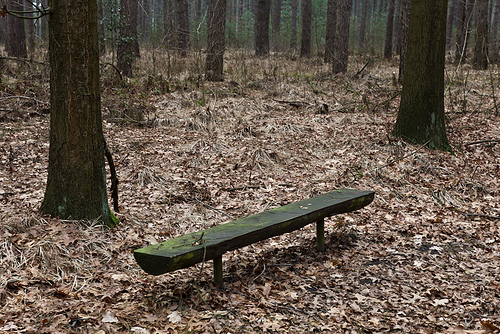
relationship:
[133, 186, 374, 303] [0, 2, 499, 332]
wooden bench in forest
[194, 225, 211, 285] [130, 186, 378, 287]
twig on wooden bench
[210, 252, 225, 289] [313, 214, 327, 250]
chair stand for leg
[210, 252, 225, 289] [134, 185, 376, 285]
chair stand for bench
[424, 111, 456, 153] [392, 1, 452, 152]
moss growing on base of tree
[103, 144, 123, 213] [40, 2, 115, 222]
branch leaning against tree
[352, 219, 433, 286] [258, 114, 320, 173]
leaves on ground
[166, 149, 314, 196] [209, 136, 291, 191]
leaves on ground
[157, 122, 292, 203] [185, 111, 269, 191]
leaves on ground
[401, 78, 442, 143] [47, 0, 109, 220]
trunk of a tree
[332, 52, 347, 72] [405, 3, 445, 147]
trunk of a tree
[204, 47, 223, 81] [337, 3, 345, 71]
trunk of a tree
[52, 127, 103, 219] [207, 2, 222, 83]
trunk of a tree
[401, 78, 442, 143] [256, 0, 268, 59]
trunk of a tree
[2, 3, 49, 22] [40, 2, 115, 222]
branch of a tree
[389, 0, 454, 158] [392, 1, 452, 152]
trunk of a tree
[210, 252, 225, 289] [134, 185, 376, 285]
chair stand of bench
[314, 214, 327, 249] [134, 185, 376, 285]
leg of bench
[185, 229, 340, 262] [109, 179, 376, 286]
leaves under bench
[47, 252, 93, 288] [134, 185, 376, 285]
leaves to left of bench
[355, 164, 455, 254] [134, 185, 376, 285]
leaves to right of bench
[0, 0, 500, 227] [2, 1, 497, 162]
trees in background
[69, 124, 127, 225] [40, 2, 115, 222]
branch against tree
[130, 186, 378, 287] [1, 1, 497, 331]
wooden bench in park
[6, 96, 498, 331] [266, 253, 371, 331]
leaves on floor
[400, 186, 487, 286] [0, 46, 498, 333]
leaves on floor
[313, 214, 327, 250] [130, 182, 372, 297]
leg of bench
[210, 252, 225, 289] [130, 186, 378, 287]
chair stand on wooden bench